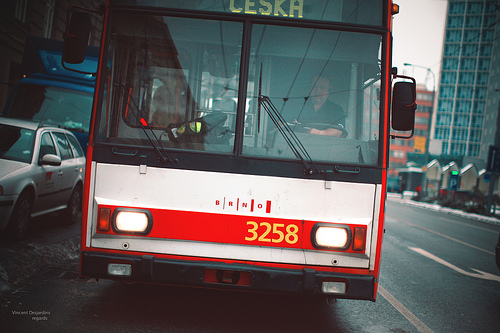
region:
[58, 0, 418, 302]
a red and white bus on the city street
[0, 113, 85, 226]
a gray car next to the bus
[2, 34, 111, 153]
a blue truck next to the bus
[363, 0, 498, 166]
tall buildings next to the bus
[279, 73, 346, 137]
man in black shirt driving the bus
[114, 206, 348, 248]
headlights on the bus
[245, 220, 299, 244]
yellow numbers on the front of the bus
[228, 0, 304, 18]
destination sign on bus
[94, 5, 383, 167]
front windshield on the bus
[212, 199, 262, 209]
small red letters on the front of the bus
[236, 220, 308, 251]
number on the bus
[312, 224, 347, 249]
headlight on the bus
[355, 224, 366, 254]
headlight on the bus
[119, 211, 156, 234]
headlight on the bus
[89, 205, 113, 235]
headlight on the bus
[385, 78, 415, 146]
side mirror on the bus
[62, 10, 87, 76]
side mirror on bus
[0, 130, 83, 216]
car on the road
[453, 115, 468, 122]
window on the building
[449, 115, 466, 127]
window on the building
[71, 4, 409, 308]
bus is red and white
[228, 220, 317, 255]
yellow numbers on bus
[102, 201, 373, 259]
white tail lights on bus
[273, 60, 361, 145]
man driving the bus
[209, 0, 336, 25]
yellow letters on bus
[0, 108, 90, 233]
car on side of bus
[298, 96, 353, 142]
driver's shirt is black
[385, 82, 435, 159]
building is red and orange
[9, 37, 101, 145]
the car is blue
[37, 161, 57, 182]
red decal on car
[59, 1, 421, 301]
a red and white public service bus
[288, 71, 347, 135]
a bus driver behind wheel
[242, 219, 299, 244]
painted bus identification number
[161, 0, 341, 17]
electronic bus destination sign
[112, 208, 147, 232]
bus front right headlight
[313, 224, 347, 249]
bus front left headlight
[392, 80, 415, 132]
a bus rearview mirror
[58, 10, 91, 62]
a bus rearview mirror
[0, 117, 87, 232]
a parked white car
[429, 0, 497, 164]
large building in distance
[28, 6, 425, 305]
person driving bus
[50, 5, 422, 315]
bus has number 3258 in front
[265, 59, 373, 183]
bus driver wearing dark shirt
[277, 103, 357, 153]
steering will is black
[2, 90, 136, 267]
car next to bus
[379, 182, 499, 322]
white marking on street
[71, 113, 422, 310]
bud head lights turned on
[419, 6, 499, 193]
glass building in background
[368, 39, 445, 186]
bus rear view mirror is black